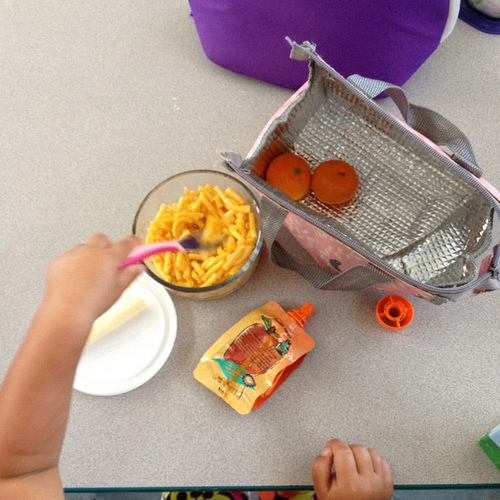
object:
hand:
[309, 438, 394, 497]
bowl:
[131, 168, 264, 303]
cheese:
[189, 259, 205, 279]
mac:
[222, 187, 246, 206]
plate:
[70, 268, 179, 396]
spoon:
[115, 227, 227, 272]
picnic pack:
[211, 36, 499, 306]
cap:
[372, 294, 412, 331]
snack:
[190, 298, 318, 415]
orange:
[311, 159, 359, 205]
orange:
[265, 153, 311, 201]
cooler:
[217, 37, 499, 306]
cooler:
[188, 1, 460, 100]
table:
[0, 0, 498, 488]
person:
[0, 232, 396, 498]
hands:
[43, 231, 145, 318]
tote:
[257, 194, 403, 292]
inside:
[220, 43, 492, 287]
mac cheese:
[221, 243, 247, 274]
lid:
[72, 282, 166, 383]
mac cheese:
[152, 261, 172, 285]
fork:
[120, 230, 228, 269]